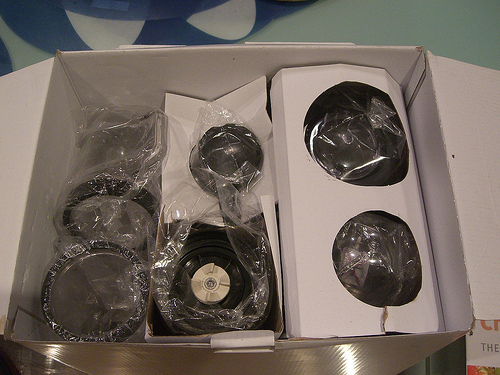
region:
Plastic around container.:
[68, 251, 184, 367]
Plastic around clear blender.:
[80, 134, 162, 214]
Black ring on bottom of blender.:
[62, 181, 171, 261]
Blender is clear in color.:
[92, 107, 181, 222]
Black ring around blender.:
[48, 239, 144, 331]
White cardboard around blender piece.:
[175, 96, 267, 220]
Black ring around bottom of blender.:
[171, 239, 262, 341]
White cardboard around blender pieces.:
[280, 117, 353, 317]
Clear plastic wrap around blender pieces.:
[353, 245, 415, 302]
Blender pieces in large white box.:
[89, 165, 346, 360]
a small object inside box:
[159, 219, 267, 336]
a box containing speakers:
[24, 40, 481, 364]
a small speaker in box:
[154, 220, 310, 331]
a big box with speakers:
[21, 24, 496, 363]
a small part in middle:
[186, 255, 254, 310]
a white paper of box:
[174, 80, 286, 225]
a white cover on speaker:
[137, 218, 307, 366]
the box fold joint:
[401, 46, 443, 89]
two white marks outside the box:
[57, 7, 292, 45]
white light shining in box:
[329, 343, 360, 373]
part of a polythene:
[318, 222, 393, 294]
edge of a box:
[420, 315, 483, 348]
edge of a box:
[193, 45, 253, 65]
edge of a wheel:
[211, 233, 240, 267]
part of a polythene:
[96, 252, 171, 319]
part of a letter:
[478, 337, 488, 356]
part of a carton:
[278, 270, 319, 330]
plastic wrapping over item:
[209, 205, 289, 248]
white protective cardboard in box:
[266, 170, 373, 314]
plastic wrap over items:
[57, 129, 168, 236]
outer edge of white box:
[138, 30, 240, 92]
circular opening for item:
[301, 86, 423, 198]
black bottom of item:
[162, 241, 273, 326]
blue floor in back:
[105, 15, 308, 57]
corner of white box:
[450, 294, 497, 344]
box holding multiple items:
[5, 45, 435, 368]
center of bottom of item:
[185, 257, 243, 314]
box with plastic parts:
[2, 36, 471, 366]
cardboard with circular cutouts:
[274, 66, 435, 332]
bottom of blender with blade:
[148, 245, 250, 325]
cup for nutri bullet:
[41, 242, 146, 336]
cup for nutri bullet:
[73, 122, 150, 243]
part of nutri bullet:
[191, 118, 261, 195]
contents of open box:
[76, 91, 414, 318]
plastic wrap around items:
[104, 112, 249, 208]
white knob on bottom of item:
[188, 263, 240, 309]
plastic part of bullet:
[183, 119, 260, 196]